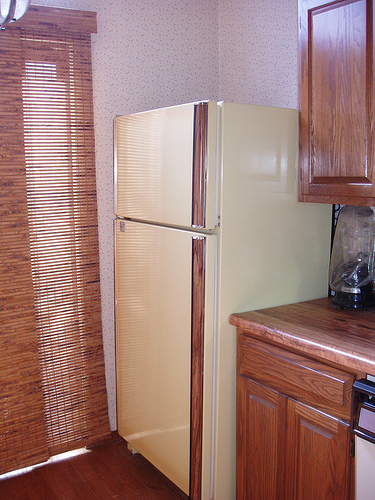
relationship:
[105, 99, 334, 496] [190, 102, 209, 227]
fridge with wood trim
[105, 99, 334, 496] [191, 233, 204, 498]
fridge with wood trim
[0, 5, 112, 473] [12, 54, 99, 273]
blinds covering window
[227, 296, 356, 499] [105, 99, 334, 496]
cabinet beside fridge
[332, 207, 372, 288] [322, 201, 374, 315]
bag covering blender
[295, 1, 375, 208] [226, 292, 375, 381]
cabinet under counter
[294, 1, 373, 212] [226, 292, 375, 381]
cabinet over counter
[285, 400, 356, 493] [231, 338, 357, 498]
door on cabinet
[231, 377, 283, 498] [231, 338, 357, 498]
door on cabinet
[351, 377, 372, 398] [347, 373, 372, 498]
top of dishwasher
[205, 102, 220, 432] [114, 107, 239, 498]
strip of fridge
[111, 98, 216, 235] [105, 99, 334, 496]
door to fridge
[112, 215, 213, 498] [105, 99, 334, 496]
door to fridge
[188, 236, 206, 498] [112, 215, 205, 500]
wood on door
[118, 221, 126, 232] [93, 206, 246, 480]
sticker on door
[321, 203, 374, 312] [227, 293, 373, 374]
appliance sitting on counter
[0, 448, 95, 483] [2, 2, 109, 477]
light shining under curtain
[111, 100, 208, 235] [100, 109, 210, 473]
door of fridge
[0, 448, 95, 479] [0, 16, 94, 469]
light beneath blinds